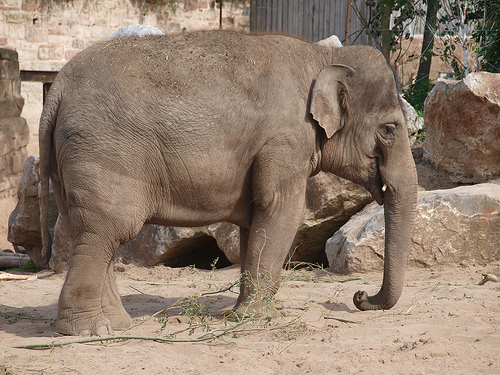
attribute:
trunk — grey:
[329, 176, 470, 351]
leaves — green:
[178, 290, 237, 342]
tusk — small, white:
[375, 178, 392, 200]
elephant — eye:
[39, 36, 407, 313]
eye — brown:
[374, 112, 400, 142]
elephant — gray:
[190, 26, 393, 177]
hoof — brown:
[231, 299, 281, 326]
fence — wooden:
[234, 3, 390, 68]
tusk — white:
[359, 180, 401, 202]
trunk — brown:
[353, 152, 418, 310]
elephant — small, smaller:
[38, 30, 416, 335]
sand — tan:
[210, 293, 444, 368]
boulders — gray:
[329, 58, 499, 280]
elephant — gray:
[131, 55, 366, 210]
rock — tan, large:
[419, 69, 485, 179]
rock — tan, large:
[320, 180, 485, 270]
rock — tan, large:
[308, 31, 423, 153]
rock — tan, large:
[206, 166, 376, 266]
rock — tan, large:
[0, 45, 30, 197]